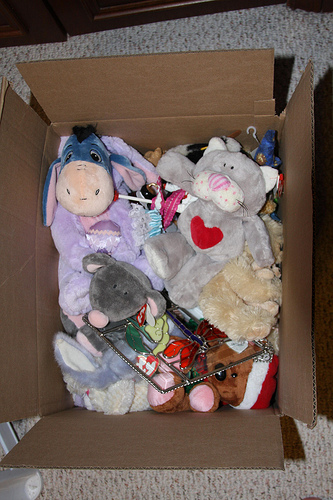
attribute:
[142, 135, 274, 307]
grey toy — stuffed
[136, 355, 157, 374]
label — ty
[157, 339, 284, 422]
bear — tedd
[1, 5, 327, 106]
carpet — brown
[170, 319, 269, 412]
teddy bear — brown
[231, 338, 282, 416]
hat — red, white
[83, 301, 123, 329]
nose — pink, large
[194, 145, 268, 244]
elephant — stuffed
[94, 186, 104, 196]
nose — pink, striped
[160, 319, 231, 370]
dragonfly — framed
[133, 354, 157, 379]
tag — red, white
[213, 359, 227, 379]
nose — black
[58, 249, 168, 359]
stuffed elephant — gray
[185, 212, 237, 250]
heart — red, large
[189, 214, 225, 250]
heart — red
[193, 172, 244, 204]
polka dots — pink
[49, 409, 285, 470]
box — cardboard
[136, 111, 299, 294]
bear — stuffed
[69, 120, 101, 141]
hair — black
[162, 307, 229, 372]
dragon fly — colorful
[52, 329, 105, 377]
ear — long, rabbit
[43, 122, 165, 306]
donkey — blue, pink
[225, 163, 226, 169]
eye — black, tiny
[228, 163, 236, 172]
eye — black, tiny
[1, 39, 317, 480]
edge — jagged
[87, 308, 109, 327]
nose — pink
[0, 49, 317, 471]
box — cardboard